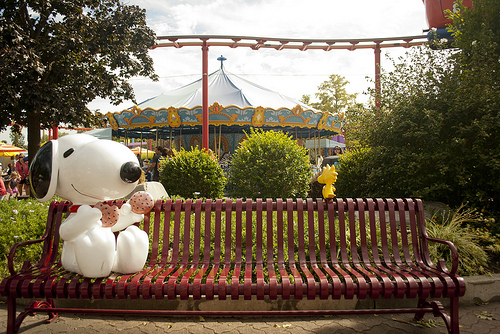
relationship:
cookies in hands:
[88, 191, 156, 233] [72, 197, 145, 229]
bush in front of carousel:
[158, 142, 225, 197] [92, 53, 347, 175]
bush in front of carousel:
[224, 126, 311, 198] [92, 53, 347, 175]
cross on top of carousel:
[210, 45, 231, 65] [110, 73, 353, 186]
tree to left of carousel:
[0, 0, 172, 154] [92, 53, 347, 175]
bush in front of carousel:
[225, 126, 314, 201] [88, 50, 350, 191]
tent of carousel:
[109, 57, 344, 134] [88, 50, 350, 191]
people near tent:
[7, 152, 36, 202] [0, 128, 40, 171]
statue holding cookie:
[311, 155, 344, 206] [126, 183, 163, 223]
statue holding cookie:
[311, 155, 344, 206] [91, 195, 131, 235]